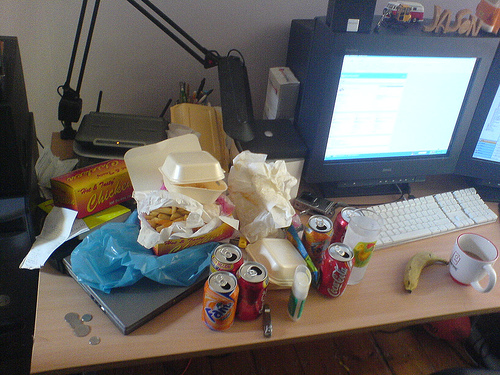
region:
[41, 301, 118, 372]
silver coins on desk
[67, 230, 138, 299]
light blue plastic bag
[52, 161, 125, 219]
red and yellow chicken take out container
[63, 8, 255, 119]
black desk lamp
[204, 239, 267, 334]
three open soda cans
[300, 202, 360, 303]
two open soda cans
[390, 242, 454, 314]
banana on desk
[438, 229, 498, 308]
white coffee mug on desk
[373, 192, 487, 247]
white computer keyboard on desk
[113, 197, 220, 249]
french fries on white paper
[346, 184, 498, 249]
a white Apple keyboard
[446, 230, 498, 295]
a white cup of cofee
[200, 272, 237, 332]
an opened soda can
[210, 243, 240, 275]
an opened soda can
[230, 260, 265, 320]
an opened soda can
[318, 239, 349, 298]
an opened soda can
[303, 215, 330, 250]
an opened soda can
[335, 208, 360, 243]
an unopened soda can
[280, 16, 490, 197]
a black computer monitor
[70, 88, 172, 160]
a wireless internet router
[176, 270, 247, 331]
orange soda can on desk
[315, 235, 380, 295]
coke soda on a desk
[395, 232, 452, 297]
banana on a desk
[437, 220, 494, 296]
cup of coffee on a desk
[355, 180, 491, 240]
key board on desk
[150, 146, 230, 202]
food container on desk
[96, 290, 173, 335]
laptop on desk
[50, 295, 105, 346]
coins on desk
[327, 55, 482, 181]
monitor on desk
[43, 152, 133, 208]
chicken box on desk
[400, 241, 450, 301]
yellow banana on desk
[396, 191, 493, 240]
white computer keyboard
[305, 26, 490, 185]
black computer monitor on desk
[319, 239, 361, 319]
open coke can on desk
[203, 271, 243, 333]
open orange fanta can on desk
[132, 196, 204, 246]
french fries in white paper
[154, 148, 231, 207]
white styrofoam sandwich container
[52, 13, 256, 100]
black desktop lamp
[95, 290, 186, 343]
laptop computer on desk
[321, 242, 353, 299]
open coca cola can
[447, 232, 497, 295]
White coffee mug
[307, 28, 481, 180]
Computer monitor screen turned on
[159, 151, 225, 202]
Sightly open styrofoam tray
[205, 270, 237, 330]
An open orange Fanta soda can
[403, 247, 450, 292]
Banana with a few brown spots on it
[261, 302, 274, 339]
Silver fingernail clips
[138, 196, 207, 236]
Paper bag full of french fries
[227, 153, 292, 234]
Crumpled up white bag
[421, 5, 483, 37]
The name Jason carved in wood